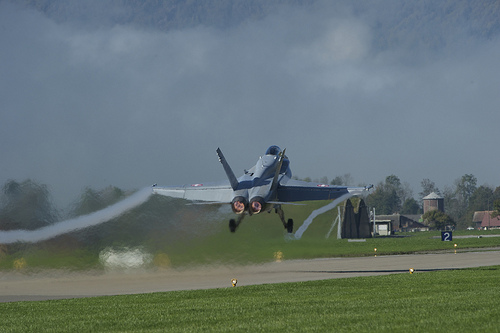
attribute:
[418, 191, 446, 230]
silo — grain, lidded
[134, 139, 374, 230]
plane — grey, taking off, hot, small, ignited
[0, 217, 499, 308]
runway — clear, paved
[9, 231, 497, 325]
grass — located, existing, present, growing, proliferating, manicured, here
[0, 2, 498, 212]
clouds — stormy, present, low lying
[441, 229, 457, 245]
sign — present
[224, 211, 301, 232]
wheels — down